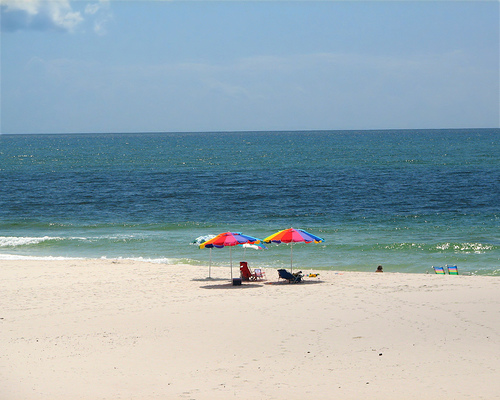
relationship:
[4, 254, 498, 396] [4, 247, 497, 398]
sand on beach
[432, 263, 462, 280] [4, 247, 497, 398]
beach chairs are on beach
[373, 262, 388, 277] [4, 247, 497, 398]
person on beach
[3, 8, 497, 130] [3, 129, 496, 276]
sky above ocean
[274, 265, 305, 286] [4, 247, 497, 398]
black chair on beach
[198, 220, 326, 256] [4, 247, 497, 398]
beach umbrellas are on beach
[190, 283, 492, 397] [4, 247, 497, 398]
footprints are on beach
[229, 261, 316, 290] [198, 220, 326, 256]
chairs are under beach umbrellas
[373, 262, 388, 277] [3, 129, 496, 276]
person in ocean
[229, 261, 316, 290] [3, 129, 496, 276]
chairs near ocean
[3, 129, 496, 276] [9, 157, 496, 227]
ocean has water section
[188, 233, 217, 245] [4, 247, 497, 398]
umbrella on beach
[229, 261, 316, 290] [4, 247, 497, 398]
chairs on beach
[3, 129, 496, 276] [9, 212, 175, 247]
ocean has waves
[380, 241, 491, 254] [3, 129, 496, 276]
ripples in ocean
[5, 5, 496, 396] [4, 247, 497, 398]
picture of beach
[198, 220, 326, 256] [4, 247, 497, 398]
beach umbrellas on beach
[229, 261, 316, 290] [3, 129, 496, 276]
chairs are by ocean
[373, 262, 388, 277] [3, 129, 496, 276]
person by ocean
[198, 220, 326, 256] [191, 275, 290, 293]
beach umbrellas cast shadows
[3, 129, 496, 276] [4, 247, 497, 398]
ocean near beach